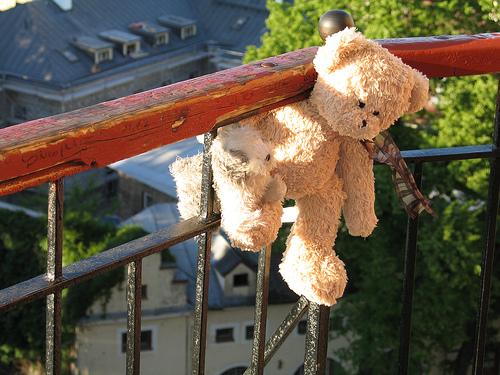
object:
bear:
[184, 40, 438, 310]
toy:
[169, 130, 286, 217]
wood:
[3, 29, 492, 180]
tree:
[249, 4, 493, 362]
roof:
[2, 1, 291, 82]